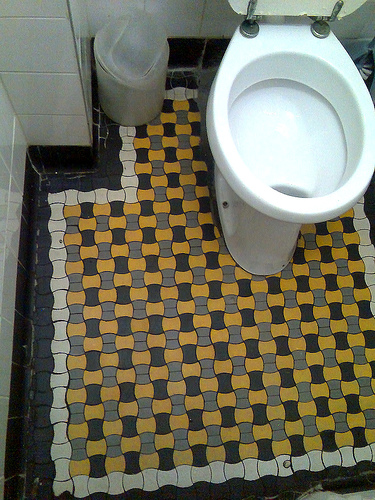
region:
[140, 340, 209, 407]
the floor is black and yellow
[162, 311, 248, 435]
the floor is black and yellow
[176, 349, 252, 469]
the floor is black and yellow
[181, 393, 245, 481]
the floor is black and yellow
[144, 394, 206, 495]
the floor is black and yellow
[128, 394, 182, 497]
the floor is black and yellow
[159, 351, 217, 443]
the floor is black and yellow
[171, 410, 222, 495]
the floor is black and yellow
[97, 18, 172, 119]
a white plastic trash can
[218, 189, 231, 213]
a metal screw in the base of the toilet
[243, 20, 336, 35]
metal grommets on the toilet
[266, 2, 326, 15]
a white lid on a toilet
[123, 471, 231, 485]
white tiles on the floor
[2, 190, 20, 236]
white tiles on the wall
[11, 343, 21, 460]
black tiles on the bottom of the wall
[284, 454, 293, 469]
a crack in the tile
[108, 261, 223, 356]
a geometric pattern of tiles on the floor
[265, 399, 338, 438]
yellow, gray and black tiles on the floor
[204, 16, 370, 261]
toilet with seat up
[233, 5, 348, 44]
metal hinges on seat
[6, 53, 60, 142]
white tiles on floor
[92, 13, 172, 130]
white plastic trash can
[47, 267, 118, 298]
tile with four colors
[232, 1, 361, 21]
bottom of upturned seat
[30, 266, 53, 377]
black tile on edge of floor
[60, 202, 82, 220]
yellow tile on floor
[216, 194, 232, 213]
bolt on bottom of toilet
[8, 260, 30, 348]
black tiles on bottom of wall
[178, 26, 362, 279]
white toilet in bathroom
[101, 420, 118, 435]
yellow tile in bathroom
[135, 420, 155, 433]
yellow tile in bathroom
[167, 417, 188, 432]
yellow tile in bathroom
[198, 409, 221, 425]
yellow tile in bathroom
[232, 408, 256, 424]
yellow tile in bathroom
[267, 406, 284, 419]
yellow tile in bathroom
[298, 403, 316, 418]
yellow tile in bathroom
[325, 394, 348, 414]
yellow tile in bathroom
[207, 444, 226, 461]
yellow tile in bathroom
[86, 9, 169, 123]
The plastic trash can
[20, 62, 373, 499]
The tiles on the ground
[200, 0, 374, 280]
The white toilet bowl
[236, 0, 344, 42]
Th silver hinges of the toilet bowl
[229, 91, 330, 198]
The water in the bowl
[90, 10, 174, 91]
The lid of the trash can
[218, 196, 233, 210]
The black mark on the bottom of the toilet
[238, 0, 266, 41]
The left toilet bowl hinge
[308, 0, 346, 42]
The right toilet hinge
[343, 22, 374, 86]
The toilet brush next to the toilet